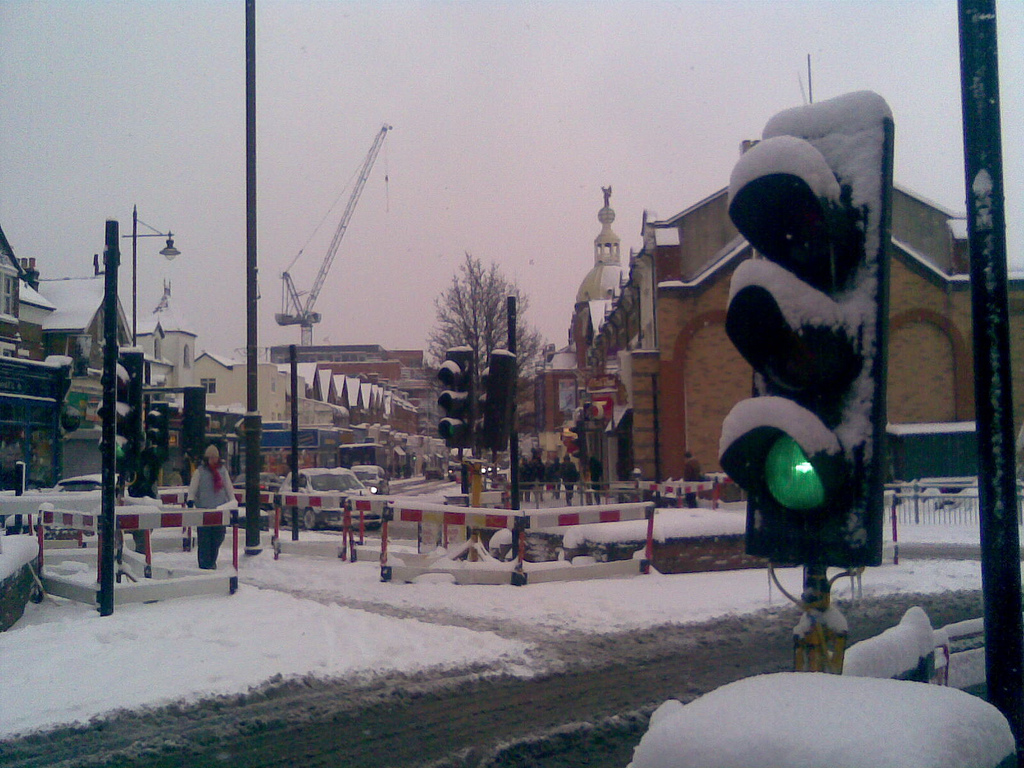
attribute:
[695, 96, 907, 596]
traffic signal — electric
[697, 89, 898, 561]
signal — electric traffic 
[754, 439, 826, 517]
light —  lit green traffic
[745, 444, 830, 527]
light — lit green traffic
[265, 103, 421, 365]
crane — tall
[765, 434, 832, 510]
light — green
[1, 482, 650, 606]
barriers — red, white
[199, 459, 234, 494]
scarf — red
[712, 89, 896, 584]
signal — electric traffic , traffic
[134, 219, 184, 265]
lamp — street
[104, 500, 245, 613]
barrier — red, white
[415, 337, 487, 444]
traffic signal — electric, snow covered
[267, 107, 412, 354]
crane — large, for lifting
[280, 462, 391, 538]
car — white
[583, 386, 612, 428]
flag — white, red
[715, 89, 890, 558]
light — black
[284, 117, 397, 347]
crane — tall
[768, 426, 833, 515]
light — green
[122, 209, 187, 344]
light — tall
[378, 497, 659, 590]
barrier — red, white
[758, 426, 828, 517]
light — green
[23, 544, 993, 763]
snow — deep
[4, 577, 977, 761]
road — slushy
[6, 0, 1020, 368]
sky — overcast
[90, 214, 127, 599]
pole — black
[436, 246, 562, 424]
tree — bare